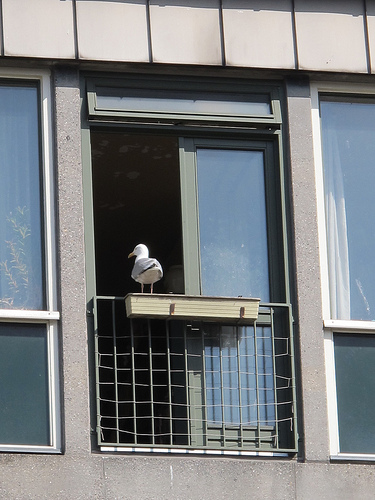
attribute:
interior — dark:
[88, 126, 190, 447]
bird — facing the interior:
[121, 237, 164, 290]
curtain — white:
[318, 95, 349, 325]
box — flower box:
[122, 286, 261, 328]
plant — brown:
[0, 202, 39, 308]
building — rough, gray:
[30, 24, 291, 393]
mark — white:
[167, 461, 173, 486]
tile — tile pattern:
[2, 0, 373, 77]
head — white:
[132, 242, 148, 257]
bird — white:
[125, 238, 166, 293]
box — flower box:
[122, 290, 263, 329]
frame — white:
[32, 74, 363, 490]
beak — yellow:
[121, 248, 136, 262]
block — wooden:
[105, 277, 272, 330]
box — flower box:
[120, 287, 272, 325]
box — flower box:
[106, 284, 273, 339]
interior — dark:
[95, 130, 182, 292]